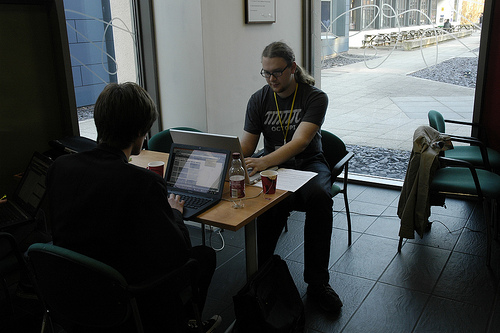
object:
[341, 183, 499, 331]
tiles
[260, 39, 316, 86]
long hair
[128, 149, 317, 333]
table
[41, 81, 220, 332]
man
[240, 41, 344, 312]
man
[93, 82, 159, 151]
hair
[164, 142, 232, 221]
laptop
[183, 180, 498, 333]
floor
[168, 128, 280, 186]
laptop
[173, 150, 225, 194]
reflection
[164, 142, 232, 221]
lap top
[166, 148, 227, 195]
screen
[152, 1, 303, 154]
wall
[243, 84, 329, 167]
shirt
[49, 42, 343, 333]
men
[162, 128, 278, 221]
laptop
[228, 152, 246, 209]
bottle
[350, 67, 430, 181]
ground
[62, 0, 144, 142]
building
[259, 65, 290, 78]
glasses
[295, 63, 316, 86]
ponytail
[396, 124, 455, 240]
jacket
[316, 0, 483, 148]
graphics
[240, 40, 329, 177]
man/lanyard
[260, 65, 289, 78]
spectacles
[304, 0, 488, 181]
window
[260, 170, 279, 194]
cup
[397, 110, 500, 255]
chair